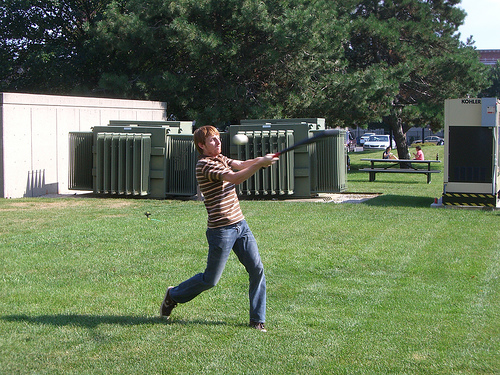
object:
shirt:
[195, 153, 244, 228]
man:
[159, 125, 279, 333]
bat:
[272, 129, 340, 158]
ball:
[233, 134, 249, 145]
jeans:
[169, 219, 267, 326]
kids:
[383, 145, 424, 160]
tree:
[0, 0, 500, 169]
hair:
[193, 125, 220, 155]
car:
[363, 135, 396, 151]